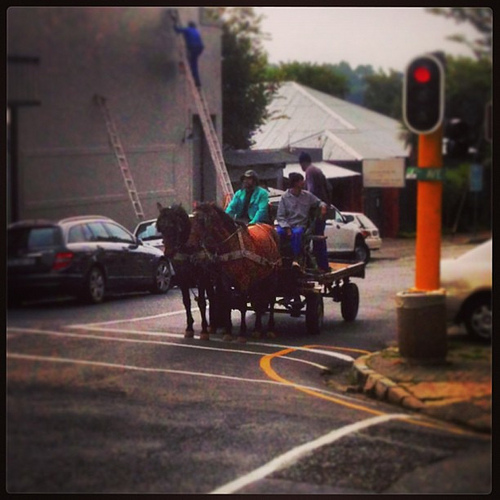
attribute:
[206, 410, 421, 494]
line — white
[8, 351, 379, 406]
line — white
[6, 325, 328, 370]
line — white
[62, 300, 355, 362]
line — white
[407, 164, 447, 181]
street sign — green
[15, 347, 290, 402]
line — white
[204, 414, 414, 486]
line — white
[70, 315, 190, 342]
line — white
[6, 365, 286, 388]
line — white, painted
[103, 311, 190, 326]
line — painted, white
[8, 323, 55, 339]
line — painted, white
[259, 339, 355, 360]
line — painted, white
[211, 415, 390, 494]
line — painted, white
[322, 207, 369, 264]
jeep — white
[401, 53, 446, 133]
light — red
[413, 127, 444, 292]
pole — orange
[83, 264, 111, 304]
tire — red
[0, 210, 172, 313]
car — grey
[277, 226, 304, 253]
blue pants — blue 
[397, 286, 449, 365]
trash can — small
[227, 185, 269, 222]
jacket — green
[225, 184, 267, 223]
coat — blue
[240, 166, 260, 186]
hat — black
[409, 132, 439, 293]
pole — orange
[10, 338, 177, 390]
line — white